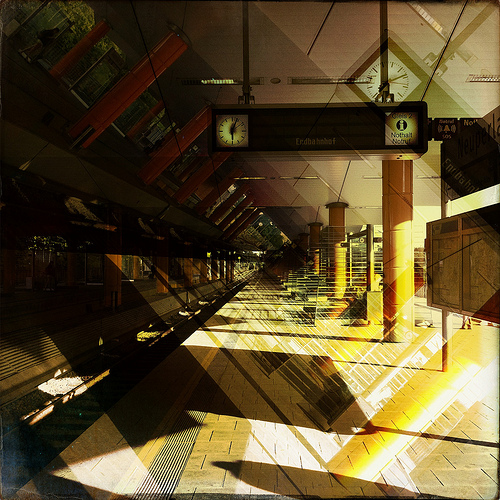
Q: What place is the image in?
A: It is at the station.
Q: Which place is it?
A: It is a station.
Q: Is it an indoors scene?
A: Yes, it is indoors.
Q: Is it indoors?
A: Yes, it is indoors.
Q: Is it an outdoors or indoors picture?
A: It is indoors.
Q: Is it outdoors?
A: No, it is indoors.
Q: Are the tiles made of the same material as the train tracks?
A: No, the tiles are made of cement and the train tracks are made of metal.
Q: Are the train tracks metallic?
A: Yes, the train tracks are metallic.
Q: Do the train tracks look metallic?
A: Yes, the train tracks are metallic.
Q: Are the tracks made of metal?
A: Yes, the tracks are made of metal.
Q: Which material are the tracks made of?
A: The tracks are made of metal.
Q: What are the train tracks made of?
A: The tracks are made of metal.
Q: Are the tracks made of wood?
A: No, the tracks are made of metal.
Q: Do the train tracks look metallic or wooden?
A: The train tracks are metallic.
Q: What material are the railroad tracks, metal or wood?
A: The railroad tracks are made of metal.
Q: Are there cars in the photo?
A: No, there are no cars.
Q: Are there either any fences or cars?
A: No, there are no cars or fences.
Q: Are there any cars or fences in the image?
A: No, there are no cars or fences.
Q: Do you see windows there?
A: Yes, there are windows.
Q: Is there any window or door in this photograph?
A: Yes, there are windows.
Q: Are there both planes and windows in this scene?
A: No, there are windows but no airplanes.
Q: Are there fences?
A: No, there are no fences.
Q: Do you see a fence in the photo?
A: No, there are no fences.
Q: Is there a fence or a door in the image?
A: No, there are no fences or doors.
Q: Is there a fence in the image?
A: No, there are no fences.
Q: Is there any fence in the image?
A: No, there are no fences.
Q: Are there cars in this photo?
A: No, there are no cars.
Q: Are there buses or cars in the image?
A: No, there are no cars or buses.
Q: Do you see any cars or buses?
A: No, there are no cars or buses.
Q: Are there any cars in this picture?
A: No, there are no cars.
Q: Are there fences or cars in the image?
A: No, there are no cars or fences.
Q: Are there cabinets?
A: No, there are no cabinets.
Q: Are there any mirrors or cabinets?
A: No, there are no cabinets or mirrors.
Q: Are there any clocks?
A: Yes, there is a clock.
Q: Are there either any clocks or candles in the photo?
A: Yes, there is a clock.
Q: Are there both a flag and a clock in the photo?
A: No, there is a clock but no flags.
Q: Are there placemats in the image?
A: No, there are no placemats.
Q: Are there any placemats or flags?
A: No, there are no placemats or flags.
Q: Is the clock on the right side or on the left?
A: The clock is on the right of the image.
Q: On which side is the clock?
A: The clock is on the right of the image.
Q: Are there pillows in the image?
A: No, there are no pillows.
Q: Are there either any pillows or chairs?
A: No, there are no pillows or chairs.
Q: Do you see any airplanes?
A: No, there are no airplanes.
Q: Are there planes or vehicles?
A: No, there are no planes or vehicles.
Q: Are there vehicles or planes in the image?
A: No, there are no planes or vehicles.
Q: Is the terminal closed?
A: Yes, the terminal is closed.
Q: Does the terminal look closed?
A: Yes, the terminal is closed.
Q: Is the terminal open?
A: No, the terminal is closed.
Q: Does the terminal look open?
A: No, the terminal is closed.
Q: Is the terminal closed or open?
A: The terminal is closed.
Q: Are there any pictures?
A: No, there are no pictures.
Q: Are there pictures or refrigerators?
A: No, there are no pictures or refrigerators.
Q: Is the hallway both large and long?
A: Yes, the hallway is large and long.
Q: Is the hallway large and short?
A: No, the hallway is large but long.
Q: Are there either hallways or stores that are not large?
A: No, there is a hallway but it is large.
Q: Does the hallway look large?
A: Yes, the hallway is large.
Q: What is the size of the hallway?
A: The hallway is large.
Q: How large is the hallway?
A: The hallway is large.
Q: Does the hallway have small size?
A: No, the hallway is large.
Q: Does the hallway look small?
A: No, the hallway is large.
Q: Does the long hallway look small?
A: No, the hallway is large.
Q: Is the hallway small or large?
A: The hallway is large.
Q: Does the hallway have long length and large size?
A: Yes, the hallway is long and large.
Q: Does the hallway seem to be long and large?
A: Yes, the hallway is long and large.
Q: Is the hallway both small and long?
A: No, the hallway is long but large.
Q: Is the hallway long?
A: Yes, the hallway is long.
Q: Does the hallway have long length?
A: Yes, the hallway is long.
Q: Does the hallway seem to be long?
A: Yes, the hallway is long.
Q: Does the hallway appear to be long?
A: Yes, the hallway is long.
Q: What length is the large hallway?
A: The hallway is long.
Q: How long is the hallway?
A: The hallway is long.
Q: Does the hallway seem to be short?
A: No, the hallway is long.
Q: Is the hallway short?
A: No, the hallway is long.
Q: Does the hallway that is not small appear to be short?
A: No, the hallway is long.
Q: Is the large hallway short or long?
A: The hallway is long.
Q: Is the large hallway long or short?
A: The hallway is long.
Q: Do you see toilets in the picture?
A: No, there are no toilets.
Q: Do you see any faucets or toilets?
A: No, there are no toilets or faucets.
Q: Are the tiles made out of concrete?
A: Yes, the tiles are made of concrete.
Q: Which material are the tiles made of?
A: The tiles are made of cement.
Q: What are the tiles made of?
A: The tiles are made of concrete.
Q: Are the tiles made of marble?
A: No, the tiles are made of cement.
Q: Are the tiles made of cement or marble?
A: The tiles are made of cement.